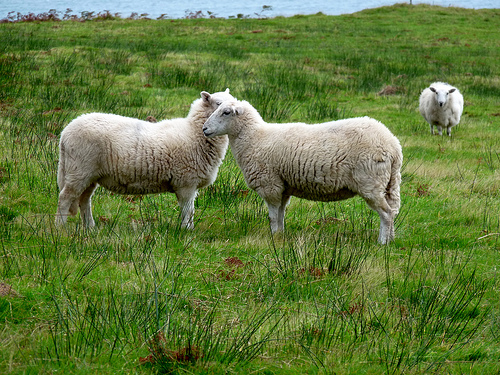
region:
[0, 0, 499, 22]
ocean in the background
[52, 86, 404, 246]
a young couple of sheep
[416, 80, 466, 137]
old sheep that looks like it could use a diet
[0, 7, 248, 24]
row of dead reddish brown bushes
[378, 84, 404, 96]
pile of dry hay-like grass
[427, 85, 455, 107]
white sheep face with rather large ears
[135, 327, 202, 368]
reddish purple weeds and/or flowers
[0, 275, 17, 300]
pile of excrement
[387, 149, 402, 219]
fluffy off-white sheep tail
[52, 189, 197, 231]
three visible legs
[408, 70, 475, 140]
fuzzy sheep in field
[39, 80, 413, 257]
two sheep standing together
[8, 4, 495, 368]
sheep standing in field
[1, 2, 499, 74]
field at water's edge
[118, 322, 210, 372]
red flowers in field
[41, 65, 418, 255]
sheep standing facing each other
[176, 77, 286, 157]
sheep with shaved face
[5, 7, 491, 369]
large sheep in field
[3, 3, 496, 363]
sheep standing very still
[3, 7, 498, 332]
sheep grazing in a field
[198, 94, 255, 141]
the head of a sheep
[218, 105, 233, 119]
the eye of a sheep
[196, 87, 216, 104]
the ear of a sheep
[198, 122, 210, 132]
the nose of a sheep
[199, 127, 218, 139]
the mouth of a sheep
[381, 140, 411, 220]
the tail of a sheep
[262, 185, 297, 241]
the front legs of a sheep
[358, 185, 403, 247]
the hind legs of a sheep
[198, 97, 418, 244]
a sheep on the grass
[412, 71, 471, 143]
a sheep in the background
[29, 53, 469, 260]
three sheep in a field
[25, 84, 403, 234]
two sheep in a field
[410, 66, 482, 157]
a sheep standing in a field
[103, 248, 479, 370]
a field of tall green grass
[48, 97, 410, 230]
two sheep standing next to each other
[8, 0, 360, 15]
a body of water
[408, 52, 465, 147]
a white sheep in a field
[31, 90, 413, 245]
two white sheep in a field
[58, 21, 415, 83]
a field of green grass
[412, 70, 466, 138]
a white sheep with big ears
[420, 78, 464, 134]
sheep walking on field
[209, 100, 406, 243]
sheep standing in field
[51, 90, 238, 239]
sheep standing in grass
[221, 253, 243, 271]
dirt pile in grass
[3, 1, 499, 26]
lake next to field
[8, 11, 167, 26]
brown plants by water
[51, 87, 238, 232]
sheep looking for food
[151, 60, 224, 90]
tall grass in field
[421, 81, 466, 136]
sheep walking for food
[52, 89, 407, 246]
two sheep in grass